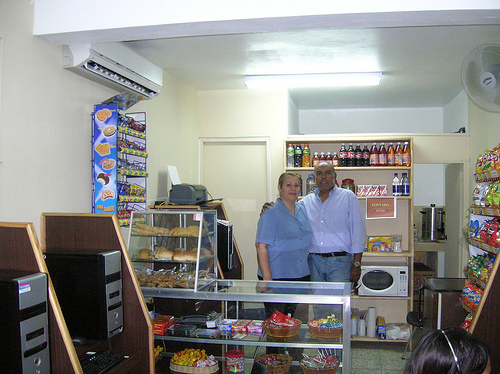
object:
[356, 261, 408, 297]
microwave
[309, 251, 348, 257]
belt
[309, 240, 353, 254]
waist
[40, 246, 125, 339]
computer cpu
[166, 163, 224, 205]
printer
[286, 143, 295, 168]
bottles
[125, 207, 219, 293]
case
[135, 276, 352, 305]
counter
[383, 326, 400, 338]
bowls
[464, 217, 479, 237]
chip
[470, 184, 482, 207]
chip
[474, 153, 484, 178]
chip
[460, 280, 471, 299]
chip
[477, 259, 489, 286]
chip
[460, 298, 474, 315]
shelf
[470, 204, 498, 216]
shelf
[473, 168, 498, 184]
shelf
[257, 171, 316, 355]
woman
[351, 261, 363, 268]
watch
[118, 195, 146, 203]
shelf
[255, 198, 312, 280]
shirt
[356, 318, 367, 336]
cups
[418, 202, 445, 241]
pot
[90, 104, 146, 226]
rack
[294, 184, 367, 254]
shirt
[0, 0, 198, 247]
painted wall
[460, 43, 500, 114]
fan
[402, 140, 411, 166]
driinks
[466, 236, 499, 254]
shelf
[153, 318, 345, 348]
shelf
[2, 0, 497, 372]
cafe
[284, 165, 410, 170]
shelf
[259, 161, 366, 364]
man